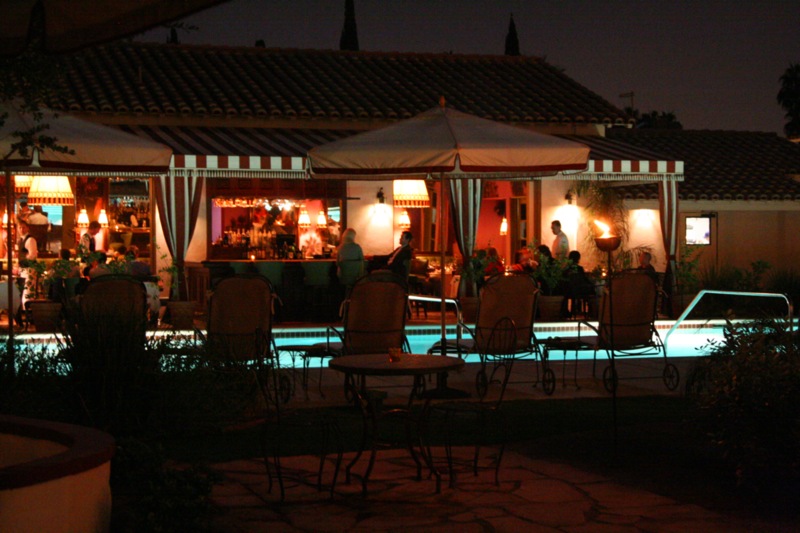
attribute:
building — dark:
[93, 319, 202, 489]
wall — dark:
[137, 102, 369, 529]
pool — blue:
[278, 233, 516, 464]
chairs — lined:
[80, 247, 762, 456]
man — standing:
[288, 195, 459, 266]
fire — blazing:
[592, 209, 613, 238]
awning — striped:
[177, 116, 796, 226]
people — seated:
[208, 143, 465, 371]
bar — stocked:
[167, 151, 306, 302]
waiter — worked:
[35, 185, 212, 410]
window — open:
[634, 154, 778, 308]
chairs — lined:
[128, 265, 638, 445]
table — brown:
[329, 324, 459, 421]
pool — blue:
[265, 279, 637, 529]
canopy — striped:
[108, 92, 398, 278]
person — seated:
[318, 218, 479, 330]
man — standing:
[529, 202, 619, 267]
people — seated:
[301, 144, 440, 308]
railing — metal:
[558, 180, 790, 354]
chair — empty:
[564, 244, 671, 353]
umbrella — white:
[390, 102, 522, 218]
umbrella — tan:
[365, 80, 619, 253]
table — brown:
[326, 344, 470, 514]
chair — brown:
[428, 270, 547, 395]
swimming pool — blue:
[9, 325, 775, 381]